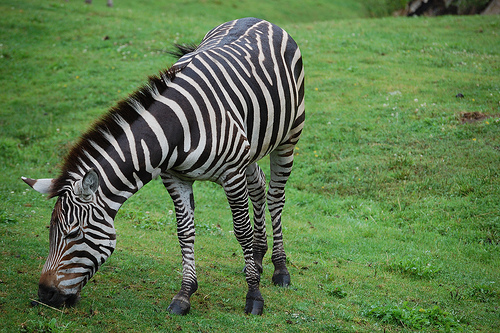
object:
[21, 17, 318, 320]
zebra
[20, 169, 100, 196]
ears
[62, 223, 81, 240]
eye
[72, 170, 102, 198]
pointy ear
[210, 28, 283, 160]
stripe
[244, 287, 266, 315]
foot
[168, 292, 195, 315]
foot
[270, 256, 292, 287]
foot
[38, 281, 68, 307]
nose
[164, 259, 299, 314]
hooves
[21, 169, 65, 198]
ear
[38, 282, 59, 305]
nose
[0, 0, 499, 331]
ground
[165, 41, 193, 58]
tail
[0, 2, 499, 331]
grass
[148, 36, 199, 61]
tail hairs